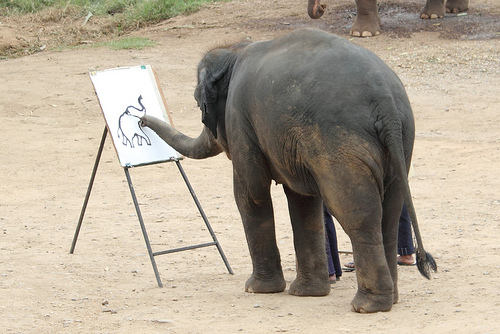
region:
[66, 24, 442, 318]
An elephant painting an elephant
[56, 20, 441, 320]
An elephant painting an elephant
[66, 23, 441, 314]
An elephant painting an elephant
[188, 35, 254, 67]
brown fuzz on elephant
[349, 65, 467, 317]
dark grey elephant tail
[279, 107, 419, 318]
dirt on back of elephant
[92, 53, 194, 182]
black picture of an elephant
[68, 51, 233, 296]
a tablet on an easel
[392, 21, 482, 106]
rocks on the ground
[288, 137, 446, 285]
person on the other side of elephant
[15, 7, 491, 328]
ground of flat brown dirt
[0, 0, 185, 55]
some grass along depression in dirt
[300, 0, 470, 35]
bottom of feet and curled trunk of nearby elephant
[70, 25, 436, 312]
baby elephant standing at easel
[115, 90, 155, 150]
trunk touching image of drawn elephant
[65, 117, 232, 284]
slanted metal supports on easel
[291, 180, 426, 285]
people's legs behind elephant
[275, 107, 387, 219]
brown dirt on belly and thigh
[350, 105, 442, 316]
tail swinging to the side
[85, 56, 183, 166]
white sheet of paper on brown backing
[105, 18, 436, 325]
this is a elephant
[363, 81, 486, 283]
tail of the elephant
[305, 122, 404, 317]
back legs of elephant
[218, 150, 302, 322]
front left leg of elephant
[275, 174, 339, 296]
right leg on elephants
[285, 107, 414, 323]
dirt on back of elephant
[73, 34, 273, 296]
elephant drawing a picture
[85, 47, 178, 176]
a black elephant drawing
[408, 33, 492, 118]
rocks on the ground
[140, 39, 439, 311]
grey elephant on dirt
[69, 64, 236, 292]
easel next to elephant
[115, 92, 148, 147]
elephant drawing on paper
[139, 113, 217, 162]
grey trunk on elephant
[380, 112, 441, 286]
grey tail on elephant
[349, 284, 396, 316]
grey foot of elephant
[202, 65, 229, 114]
grey ear on elephant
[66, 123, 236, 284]
black metal easel legs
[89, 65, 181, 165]
white paper on easel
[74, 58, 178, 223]
Elephant made to appear to be painting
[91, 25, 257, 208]
Animal has its trunk on the canvas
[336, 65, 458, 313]
Animal has a very long tail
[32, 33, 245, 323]
Easel is made of metal on the frame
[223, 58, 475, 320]
People are hidden on the other side of the elephant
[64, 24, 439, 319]
grey elephant painting picture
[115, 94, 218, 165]
elephant trunk with paint brush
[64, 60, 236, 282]
outline of elephant on paper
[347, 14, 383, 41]
white toe nails of elephant foot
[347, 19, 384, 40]
white toe nails of elephant foot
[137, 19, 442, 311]
elephant painting with her trunk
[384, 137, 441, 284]
swinging tail of the lephant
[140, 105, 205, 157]
trunk of the elephant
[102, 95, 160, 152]
black outline drawing of an elephant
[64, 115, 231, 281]
easel the paper pad is on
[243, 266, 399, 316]
feet of the elephant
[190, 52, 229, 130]
ear of the elephant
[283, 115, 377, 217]
brown spot on the elephant's leg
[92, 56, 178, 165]
white paper the drawing is on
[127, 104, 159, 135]
elephant holding a paintbrush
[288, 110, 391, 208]
dirt on the elephant leg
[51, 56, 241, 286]
picture on the tripod